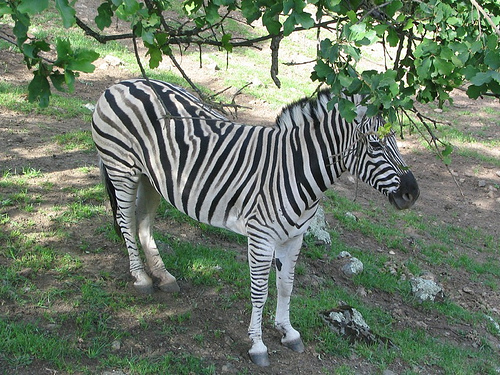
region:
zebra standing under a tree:
[84, 51, 441, 356]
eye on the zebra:
[361, 135, 389, 157]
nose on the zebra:
[382, 165, 426, 216]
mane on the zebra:
[272, 92, 314, 137]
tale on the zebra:
[92, 153, 125, 233]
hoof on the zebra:
[282, 326, 314, 368]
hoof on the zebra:
[253, 331, 275, 368]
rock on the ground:
[322, 297, 379, 353]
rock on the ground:
[410, 258, 451, 312]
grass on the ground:
[7, 315, 75, 361]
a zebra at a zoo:
[63, 14, 459, 370]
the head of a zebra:
[321, 85, 426, 217]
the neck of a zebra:
[279, 103, 351, 202]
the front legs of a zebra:
[228, 237, 308, 366]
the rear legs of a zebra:
[110, 171, 187, 296]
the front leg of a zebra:
[236, 240, 278, 371]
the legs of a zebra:
[93, 178, 335, 368]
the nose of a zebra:
[386, 171, 422, 211]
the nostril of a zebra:
[399, 189, 411, 201]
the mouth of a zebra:
[388, 191, 402, 209]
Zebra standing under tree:
[85, 88, 414, 355]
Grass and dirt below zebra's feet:
[85, 208, 402, 366]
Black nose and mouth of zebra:
[385, 173, 432, 226]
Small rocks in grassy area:
[338, 238, 375, 284]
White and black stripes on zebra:
[145, 93, 362, 238]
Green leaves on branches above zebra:
[238, 23, 495, 116]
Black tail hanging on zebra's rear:
[94, 148, 152, 290]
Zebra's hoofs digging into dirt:
[238, 318, 312, 374]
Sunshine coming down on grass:
[185, 10, 407, 121]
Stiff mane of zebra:
[277, 84, 394, 141]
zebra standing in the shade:
[25, 5, 452, 365]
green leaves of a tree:
[0, 0, 495, 155]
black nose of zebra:
[385, 165, 415, 205]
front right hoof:
[242, 345, 268, 365]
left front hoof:
[280, 335, 305, 355]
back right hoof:
[130, 276, 160, 291]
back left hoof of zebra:
[155, 280, 180, 290]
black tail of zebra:
[100, 165, 116, 245]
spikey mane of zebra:
[273, 85, 390, 127]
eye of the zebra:
[367, 137, 381, 148]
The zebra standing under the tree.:
[74, 52, 421, 363]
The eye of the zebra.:
[362, 132, 386, 149]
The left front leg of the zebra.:
[235, 232, 282, 364]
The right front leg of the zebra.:
[277, 242, 310, 354]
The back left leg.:
[108, 170, 148, 290]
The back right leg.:
[130, 175, 182, 289]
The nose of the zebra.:
[391, 180, 422, 200]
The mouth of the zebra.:
[389, 199, 416, 211]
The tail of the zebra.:
[92, 153, 119, 229]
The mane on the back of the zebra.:
[280, 83, 385, 127]